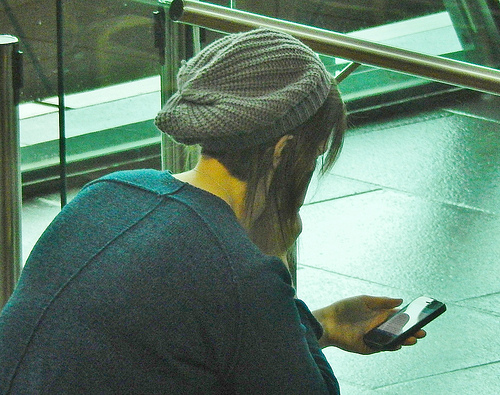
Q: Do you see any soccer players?
A: No, there are no soccer players.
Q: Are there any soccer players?
A: No, there are no soccer players.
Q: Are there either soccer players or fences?
A: No, there are no soccer players or fences.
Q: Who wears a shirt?
A: The girl wears a shirt.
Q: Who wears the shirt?
A: The girl wears a shirt.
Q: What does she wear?
A: The girl wears a shirt.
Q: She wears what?
A: The girl wears a shirt.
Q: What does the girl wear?
A: The girl wears a shirt.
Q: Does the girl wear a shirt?
A: Yes, the girl wears a shirt.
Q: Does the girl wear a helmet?
A: No, the girl wears a shirt.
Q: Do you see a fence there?
A: No, there are no fences.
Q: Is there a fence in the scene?
A: No, there are no fences.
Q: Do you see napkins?
A: No, there are no napkins.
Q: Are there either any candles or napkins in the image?
A: No, there are no napkins or candles.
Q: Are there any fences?
A: No, there are no fences.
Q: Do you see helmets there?
A: No, there are no helmets.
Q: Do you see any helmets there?
A: No, there are no helmets.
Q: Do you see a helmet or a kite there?
A: No, there are no helmets or kites.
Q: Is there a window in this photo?
A: Yes, there is a window.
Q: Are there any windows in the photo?
A: Yes, there is a window.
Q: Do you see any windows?
A: Yes, there is a window.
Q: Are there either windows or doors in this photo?
A: Yes, there is a window.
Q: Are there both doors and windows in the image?
A: No, there is a window but no doors.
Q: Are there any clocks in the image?
A: No, there are no clocks.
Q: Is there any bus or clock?
A: No, there are no clocks or buses.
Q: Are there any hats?
A: Yes, there is a hat.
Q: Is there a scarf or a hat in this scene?
A: Yes, there is a hat.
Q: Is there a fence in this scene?
A: No, there are no fences.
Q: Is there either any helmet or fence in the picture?
A: No, there are no fences or helmets.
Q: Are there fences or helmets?
A: No, there are no fences or helmets.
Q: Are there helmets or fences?
A: No, there are no fences or helmets.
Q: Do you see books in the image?
A: No, there are no books.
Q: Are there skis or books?
A: No, there are no books or skis.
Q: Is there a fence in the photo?
A: No, there are no fences.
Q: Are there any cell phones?
A: Yes, there is a cell phone.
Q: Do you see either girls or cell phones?
A: Yes, there is a cell phone.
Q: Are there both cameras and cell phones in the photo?
A: No, there is a cell phone but no cameras.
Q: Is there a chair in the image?
A: No, there are no chairs.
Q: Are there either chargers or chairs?
A: No, there are no chairs or chargers.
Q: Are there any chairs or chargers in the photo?
A: No, there are no chairs or chargers.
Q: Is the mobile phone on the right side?
A: Yes, the mobile phone is on the right of the image.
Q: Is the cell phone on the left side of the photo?
A: No, the cell phone is on the right of the image.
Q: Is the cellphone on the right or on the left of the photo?
A: The cellphone is on the right of the image.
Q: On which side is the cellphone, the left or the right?
A: The cellphone is on the right of the image.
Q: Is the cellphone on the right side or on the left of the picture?
A: The cellphone is on the right of the image.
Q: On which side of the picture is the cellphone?
A: The cellphone is on the right of the image.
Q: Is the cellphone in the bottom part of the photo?
A: Yes, the cellphone is in the bottom of the image.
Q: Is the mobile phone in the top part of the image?
A: No, the mobile phone is in the bottom of the image.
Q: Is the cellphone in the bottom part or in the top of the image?
A: The cellphone is in the bottom of the image.